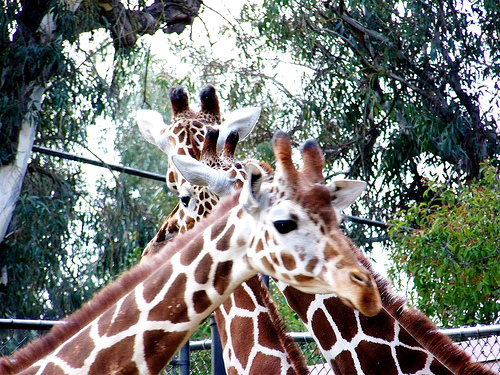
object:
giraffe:
[0, 133, 382, 375]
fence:
[0, 317, 499, 375]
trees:
[238, 0, 497, 180]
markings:
[0, 129, 384, 374]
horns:
[272, 130, 298, 191]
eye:
[272, 219, 298, 234]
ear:
[238, 162, 264, 215]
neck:
[0, 187, 259, 375]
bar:
[31, 144, 421, 233]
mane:
[0, 190, 243, 375]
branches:
[320, 1, 453, 119]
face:
[250, 191, 382, 318]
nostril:
[354, 274, 363, 281]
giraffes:
[136, 129, 491, 375]